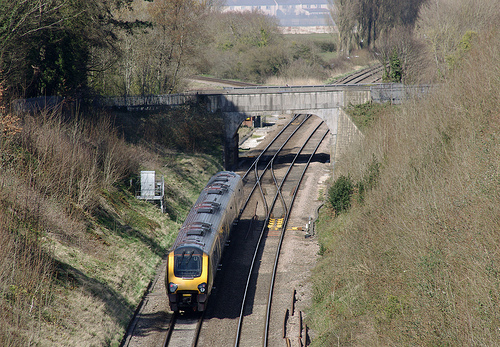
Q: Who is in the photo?
A: Nobody.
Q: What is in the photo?
A: A train.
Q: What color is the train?
A: Black.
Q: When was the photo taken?
A: During the day.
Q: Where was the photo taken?
A: Train tracks.